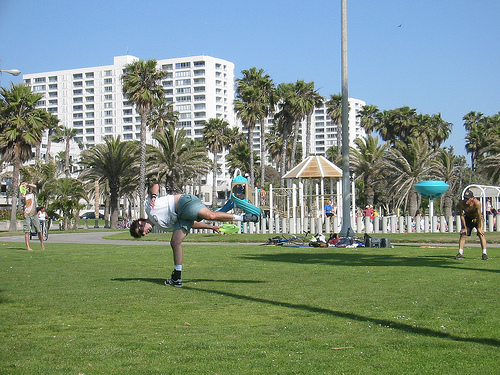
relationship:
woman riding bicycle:
[35, 205, 51, 222] [23, 217, 51, 241]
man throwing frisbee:
[15, 178, 48, 253] [16, 181, 28, 197]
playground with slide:
[207, 152, 498, 247] [226, 187, 264, 225]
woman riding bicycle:
[34, 205, 51, 222] [29, 217, 51, 238]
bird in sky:
[396, 21, 403, 27] [0, 0, 499, 170]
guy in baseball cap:
[450, 187, 487, 261] [460, 189, 473, 198]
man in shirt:
[128, 173, 275, 290] [144, 190, 186, 234]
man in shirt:
[16, 181, 46, 252] [22, 186, 39, 216]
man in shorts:
[129, 174, 260, 284] [171, 192, 205, 234]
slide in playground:
[223, 174, 261, 219] [174, 155, 496, 240]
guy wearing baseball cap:
[452, 187, 492, 264] [460, 187, 477, 198]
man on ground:
[129, 174, 260, 284] [15, 221, 497, 365]